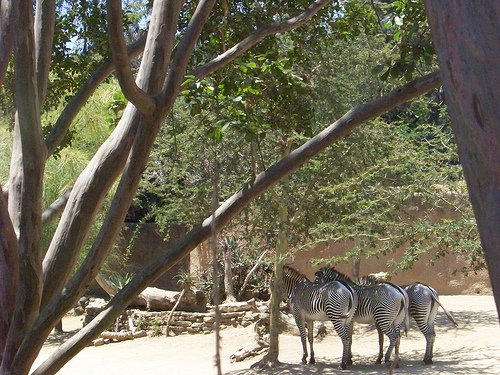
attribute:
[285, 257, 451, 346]
zebras — three, white, black, plump, short, thin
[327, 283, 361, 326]
butts — angeled, pointed, curved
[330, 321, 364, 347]
leg — white, black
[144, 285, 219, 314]
log — brown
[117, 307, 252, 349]
wall — brown, tan, low, smooth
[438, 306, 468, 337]
tails — straight, curved, black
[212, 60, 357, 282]
trees — curved, green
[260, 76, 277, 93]
leaves — green, long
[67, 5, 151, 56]
sky — blue